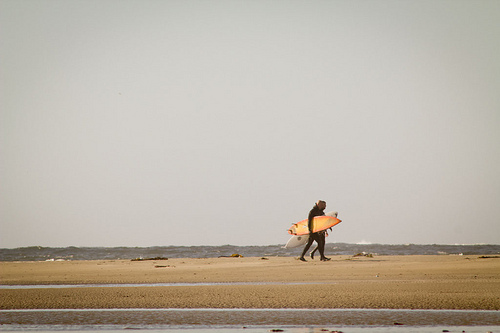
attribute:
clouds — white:
[0, 2, 498, 251]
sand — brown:
[1, 255, 498, 307]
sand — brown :
[368, 277, 404, 288]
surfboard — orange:
[288, 212, 339, 234]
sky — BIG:
[52, 35, 441, 176]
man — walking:
[299, 193, 329, 261]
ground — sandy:
[2, 254, 499, 312]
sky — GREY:
[4, 4, 498, 180]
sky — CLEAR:
[29, 24, 266, 206]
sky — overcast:
[34, 72, 226, 211]